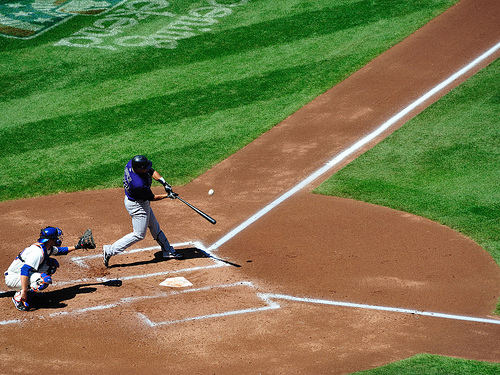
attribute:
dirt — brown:
[0, 0, 499, 372]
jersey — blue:
[120, 162, 159, 206]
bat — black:
[157, 177, 219, 227]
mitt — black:
[73, 227, 97, 251]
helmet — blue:
[35, 222, 65, 245]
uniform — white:
[0, 240, 70, 295]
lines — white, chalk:
[2, 47, 499, 367]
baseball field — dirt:
[3, 0, 498, 370]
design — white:
[0, 0, 244, 56]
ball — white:
[200, 174, 224, 208]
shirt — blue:
[120, 160, 154, 205]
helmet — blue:
[129, 153, 157, 172]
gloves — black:
[162, 181, 176, 202]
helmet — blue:
[32, 224, 75, 258]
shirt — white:
[25, 242, 49, 281]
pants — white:
[7, 262, 39, 292]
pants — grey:
[116, 197, 156, 246]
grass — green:
[83, 55, 217, 152]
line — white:
[327, 291, 445, 340]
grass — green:
[86, 30, 264, 164]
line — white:
[264, 100, 375, 250]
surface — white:
[151, 276, 213, 302]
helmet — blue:
[35, 222, 60, 245]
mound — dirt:
[6, 196, 448, 373]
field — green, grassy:
[2, 0, 484, 370]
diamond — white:
[155, 273, 194, 292]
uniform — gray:
[112, 196, 168, 250]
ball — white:
[202, 187, 221, 200]